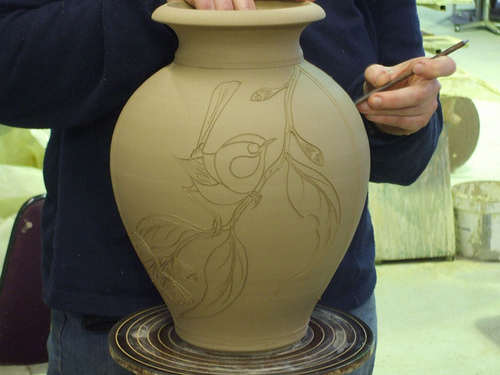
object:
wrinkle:
[86, 15, 123, 116]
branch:
[122, 63, 327, 322]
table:
[0, 0, 500, 375]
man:
[1, 1, 456, 373]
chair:
[0, 193, 56, 368]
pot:
[108, 2, 370, 354]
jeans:
[48, 290, 373, 373]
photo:
[4, 3, 500, 375]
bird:
[174, 133, 278, 209]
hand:
[357, 55, 458, 138]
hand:
[181, 1, 261, 12]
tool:
[352, 38, 472, 106]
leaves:
[147, 215, 251, 330]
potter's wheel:
[104, 302, 372, 375]